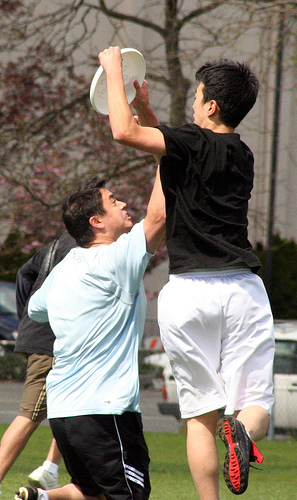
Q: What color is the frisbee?
A: White.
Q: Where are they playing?
A: Park.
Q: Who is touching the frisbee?
A: The guy in the white shorts.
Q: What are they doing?
A: Playing Frisbee.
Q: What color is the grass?
A: Green.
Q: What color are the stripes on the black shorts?
A: White.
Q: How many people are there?
A: Three.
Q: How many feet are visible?
A: Three.